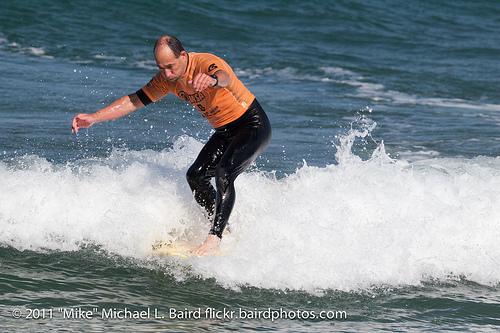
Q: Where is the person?
A: In the ocean.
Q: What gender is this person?
A: This person is a male.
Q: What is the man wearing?
A: A wetsuit.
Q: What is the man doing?
A: The man is surfing.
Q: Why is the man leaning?
A: To keep his balance.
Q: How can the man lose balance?
A: If a large wave hits him.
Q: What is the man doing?
A: Surfing.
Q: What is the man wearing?
A: Wetsuit.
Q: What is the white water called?
A: Rapids.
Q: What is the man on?
A: Surfboard.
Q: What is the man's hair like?
A: Bald.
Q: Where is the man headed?
A: The shore.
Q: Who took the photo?
A: Michael L. Baird.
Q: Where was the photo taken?
A: At the ocean.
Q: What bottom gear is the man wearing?
A: Wetsuit.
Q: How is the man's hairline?
A: Balding.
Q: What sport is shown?
A: Surfing.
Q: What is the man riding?
A: A surfboard.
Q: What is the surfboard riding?
A: Waves.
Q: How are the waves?
A: Small.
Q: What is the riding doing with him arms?
A: Balancing.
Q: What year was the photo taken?
A: 2011.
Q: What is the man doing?
A: Surfing.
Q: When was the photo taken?
A: Daytime.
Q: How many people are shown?
A: One.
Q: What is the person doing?
A: Surfing.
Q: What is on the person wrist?
A: Watch.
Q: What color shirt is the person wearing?
A: Orange.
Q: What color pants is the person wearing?
A: Black.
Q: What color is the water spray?
A: White.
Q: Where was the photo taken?
A: Water.